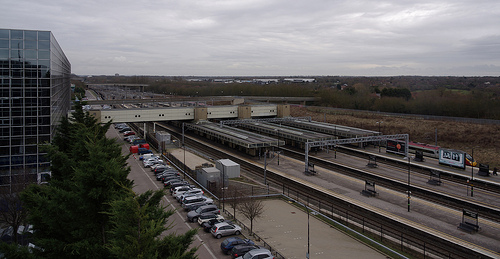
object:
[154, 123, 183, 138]
entrance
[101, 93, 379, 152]
station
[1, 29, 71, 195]
building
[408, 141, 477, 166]
train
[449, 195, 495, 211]
track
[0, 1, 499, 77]
sky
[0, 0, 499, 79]
clouds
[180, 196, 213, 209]
car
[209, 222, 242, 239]
car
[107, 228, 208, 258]
tree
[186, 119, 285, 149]
awning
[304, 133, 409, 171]
structure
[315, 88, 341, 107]
tree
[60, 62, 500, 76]
distance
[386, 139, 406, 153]
sign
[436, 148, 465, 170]
platform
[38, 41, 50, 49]
window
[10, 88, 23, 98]
window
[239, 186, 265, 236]
tree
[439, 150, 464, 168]
sign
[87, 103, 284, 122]
bridge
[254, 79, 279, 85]
building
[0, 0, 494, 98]
background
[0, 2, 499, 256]
day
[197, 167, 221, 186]
box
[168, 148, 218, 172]
building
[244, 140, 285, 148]
terminal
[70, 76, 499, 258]
ground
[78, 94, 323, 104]
overpass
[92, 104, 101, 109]
road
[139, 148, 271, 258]
row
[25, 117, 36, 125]
glass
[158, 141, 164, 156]
gate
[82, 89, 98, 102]
freeway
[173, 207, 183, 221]
line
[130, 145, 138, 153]
container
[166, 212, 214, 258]
street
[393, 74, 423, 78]
hill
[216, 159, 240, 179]
container